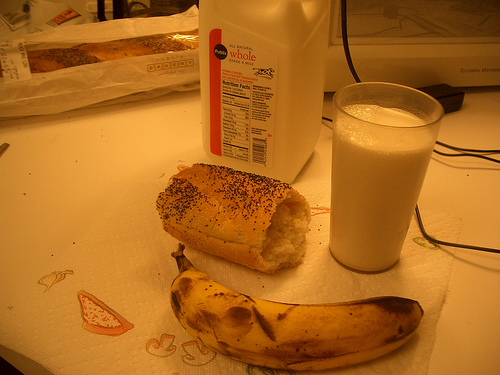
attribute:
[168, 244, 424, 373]
banana — yellow, brown, unpeeled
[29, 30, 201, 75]
bread — loaf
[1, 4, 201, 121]
bag — plastic, white, clear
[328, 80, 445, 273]
glass — clear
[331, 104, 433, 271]
milk — white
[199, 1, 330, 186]
container — plastic, white, milk, whole milk, half gallon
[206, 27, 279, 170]
label — white black, red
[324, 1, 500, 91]
microwave — white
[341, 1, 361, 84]
cord — black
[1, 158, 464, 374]
tissue — white, patterned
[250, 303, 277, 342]
bruise — brown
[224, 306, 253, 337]
bruise — brown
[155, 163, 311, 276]
bread — chunk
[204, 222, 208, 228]
seed — brown, poppy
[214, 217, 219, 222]
seed — brown, poppy